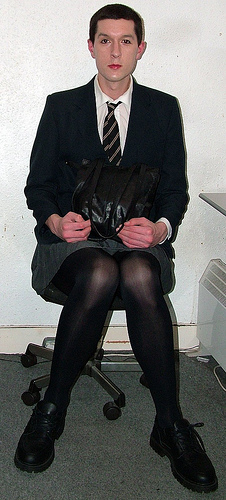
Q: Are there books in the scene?
A: No, there are no books.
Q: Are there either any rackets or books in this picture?
A: No, there are no books or rackets.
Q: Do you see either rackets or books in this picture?
A: No, there are no books or rackets.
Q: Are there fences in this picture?
A: No, there are no fences.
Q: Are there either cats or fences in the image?
A: No, there are no fences or cats.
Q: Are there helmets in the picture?
A: No, there are no helmets.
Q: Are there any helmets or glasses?
A: No, there are no helmets or glasses.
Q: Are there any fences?
A: No, there are no fences.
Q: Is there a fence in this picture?
A: No, there are no fences.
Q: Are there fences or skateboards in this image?
A: No, there are no fences or skateboards.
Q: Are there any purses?
A: Yes, there is a purse.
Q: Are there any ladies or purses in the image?
A: Yes, there is a purse.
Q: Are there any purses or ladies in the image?
A: Yes, there is a purse.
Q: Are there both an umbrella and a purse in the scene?
A: No, there is a purse but no umbrellas.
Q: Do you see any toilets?
A: No, there are no toilets.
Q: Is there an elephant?
A: No, there are no elephants.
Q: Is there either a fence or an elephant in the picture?
A: No, there are no elephants or fences.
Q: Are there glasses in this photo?
A: No, there are no glasses.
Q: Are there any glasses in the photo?
A: No, there are no glasses.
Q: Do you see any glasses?
A: No, there are no glasses.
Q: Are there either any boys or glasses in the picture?
A: No, there are no glasses or boys.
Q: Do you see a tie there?
A: Yes, there is a tie.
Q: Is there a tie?
A: Yes, there is a tie.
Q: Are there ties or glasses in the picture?
A: Yes, there is a tie.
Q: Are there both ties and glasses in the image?
A: No, there is a tie but no glasses.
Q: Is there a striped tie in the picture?
A: Yes, there is a striped tie.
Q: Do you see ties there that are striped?
A: Yes, there is a tie that is striped.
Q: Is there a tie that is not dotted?
A: Yes, there is a striped tie.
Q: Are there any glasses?
A: No, there are no glasses.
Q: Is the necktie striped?
A: Yes, the necktie is striped.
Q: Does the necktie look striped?
A: Yes, the necktie is striped.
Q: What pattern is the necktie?
A: The necktie is striped.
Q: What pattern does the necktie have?
A: The necktie has striped pattern.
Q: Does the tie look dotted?
A: No, the tie is striped.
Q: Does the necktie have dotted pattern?
A: No, the necktie is striped.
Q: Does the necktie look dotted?
A: No, the necktie is striped.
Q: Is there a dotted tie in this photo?
A: No, there is a tie but it is striped.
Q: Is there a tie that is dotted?
A: No, there is a tie but it is striped.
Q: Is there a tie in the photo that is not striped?
A: No, there is a tie but it is striped.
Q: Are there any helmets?
A: No, there are no helmets.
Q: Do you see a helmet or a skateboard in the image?
A: No, there are no helmets or skateboards.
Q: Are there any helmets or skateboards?
A: No, there are no helmets or skateboards.